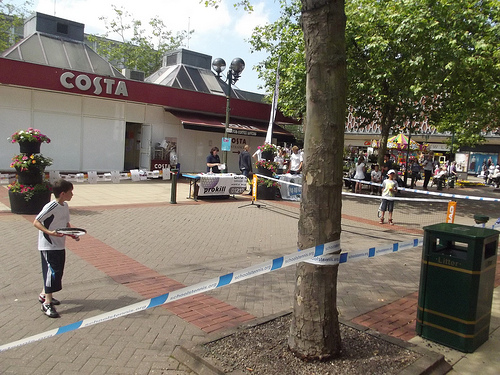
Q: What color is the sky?
A: Blue.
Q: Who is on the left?
A: The boy.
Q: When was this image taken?
A: Daytime.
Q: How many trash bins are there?
A: One.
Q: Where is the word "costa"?
A: On the building.